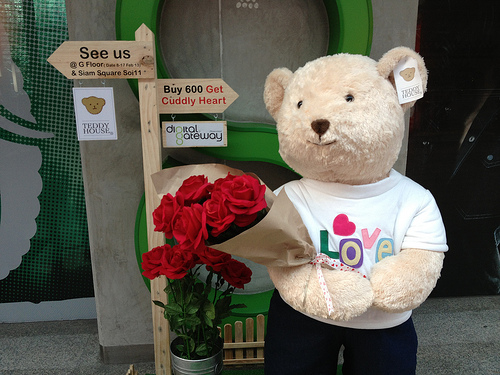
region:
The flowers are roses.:
[140, 165, 263, 281]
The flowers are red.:
[135, 165, 263, 282]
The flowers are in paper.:
[138, 158, 310, 286]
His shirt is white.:
[270, 162, 425, 329]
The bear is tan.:
[235, 39, 443, 364]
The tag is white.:
[390, 53, 435, 115]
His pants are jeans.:
[255, 307, 418, 371]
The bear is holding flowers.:
[130, 40, 431, 367]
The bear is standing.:
[142, 43, 453, 357]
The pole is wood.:
[125, 32, 185, 374]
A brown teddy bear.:
[261, 50, 443, 372]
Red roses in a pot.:
[143, 242, 245, 372]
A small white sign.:
[71, 88, 121, 145]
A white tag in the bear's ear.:
[393, 56, 420, 101]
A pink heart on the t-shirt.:
[333, 210, 358, 237]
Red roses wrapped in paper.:
[151, 170, 314, 267]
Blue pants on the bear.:
[266, 320, 415, 374]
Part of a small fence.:
[225, 318, 263, 359]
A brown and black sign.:
[48, 42, 156, 79]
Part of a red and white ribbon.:
[316, 254, 353, 271]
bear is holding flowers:
[117, 31, 498, 373]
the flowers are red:
[108, 161, 293, 297]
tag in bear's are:
[382, 51, 427, 109]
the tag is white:
[374, 46, 436, 118]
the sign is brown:
[20, 13, 192, 104]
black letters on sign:
[42, 42, 177, 98]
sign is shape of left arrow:
[24, 17, 169, 94]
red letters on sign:
[155, 75, 244, 122]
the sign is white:
[162, 110, 237, 151]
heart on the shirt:
[324, 213, 370, 243]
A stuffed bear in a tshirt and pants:
[246, 45, 441, 370]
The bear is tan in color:
[280, 44, 411, 182]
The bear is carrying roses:
[211, 90, 440, 331]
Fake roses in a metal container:
[143, 248, 236, 373]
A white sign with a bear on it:
[76, 77, 118, 146]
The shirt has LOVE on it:
[308, 215, 413, 281]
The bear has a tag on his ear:
[376, 47, 426, 109]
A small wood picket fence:
[221, 308, 268, 369]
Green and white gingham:
[46, 159, 85, 251]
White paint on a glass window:
[8, 198, 76, 286]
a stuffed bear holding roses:
[155, 51, 447, 374]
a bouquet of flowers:
[149, 166, 359, 275]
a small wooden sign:
[49, 25, 236, 374]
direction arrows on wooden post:
[51, 37, 240, 115]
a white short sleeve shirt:
[272, 175, 447, 322]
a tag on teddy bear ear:
[386, 57, 425, 103]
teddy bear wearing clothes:
[261, 48, 449, 374]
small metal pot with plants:
[167, 336, 221, 374]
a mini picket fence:
[200, 314, 267, 366]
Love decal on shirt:
[319, 215, 396, 268]